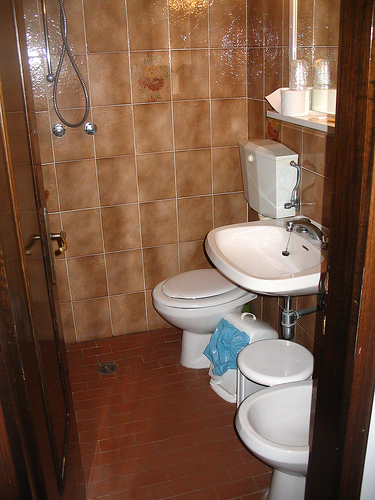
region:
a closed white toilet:
[152, 267, 255, 370]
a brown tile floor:
[75, 402, 216, 494]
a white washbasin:
[203, 217, 335, 294]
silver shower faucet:
[37, 0, 106, 136]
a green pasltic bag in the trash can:
[203, 318, 253, 376]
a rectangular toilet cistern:
[230, 135, 301, 218]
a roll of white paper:
[264, 87, 309, 115]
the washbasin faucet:
[285, 218, 321, 245]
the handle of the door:
[46, 231, 66, 251]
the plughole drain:
[101, 362, 114, 374]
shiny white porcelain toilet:
[146, 259, 259, 373]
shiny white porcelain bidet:
[234, 374, 331, 498]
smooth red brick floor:
[47, 326, 275, 499]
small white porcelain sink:
[189, 205, 328, 297]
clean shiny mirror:
[292, 0, 346, 123]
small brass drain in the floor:
[94, 354, 118, 375]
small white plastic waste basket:
[203, 311, 280, 407]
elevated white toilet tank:
[234, 135, 302, 223]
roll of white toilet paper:
[263, 80, 312, 119]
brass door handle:
[47, 226, 69, 261]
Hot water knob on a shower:
[52, 124, 65, 135]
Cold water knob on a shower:
[83, 121, 96, 135]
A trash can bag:
[205, 319, 248, 375]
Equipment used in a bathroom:
[234, 337, 313, 405]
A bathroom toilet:
[233, 379, 320, 499]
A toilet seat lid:
[153, 267, 247, 306]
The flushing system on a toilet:
[237, 139, 299, 217]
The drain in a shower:
[98, 361, 118, 374]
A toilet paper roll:
[264, 87, 310, 115]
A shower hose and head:
[40, 0, 89, 126]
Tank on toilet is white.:
[237, 140, 297, 207]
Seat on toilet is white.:
[164, 263, 233, 316]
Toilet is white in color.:
[153, 260, 199, 370]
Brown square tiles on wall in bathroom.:
[79, 198, 169, 259]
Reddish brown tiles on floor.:
[102, 396, 182, 463]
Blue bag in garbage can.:
[212, 320, 246, 367]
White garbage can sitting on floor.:
[210, 315, 253, 418]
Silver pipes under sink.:
[279, 296, 307, 339]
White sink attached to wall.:
[238, 229, 316, 285]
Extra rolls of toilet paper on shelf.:
[274, 81, 328, 111]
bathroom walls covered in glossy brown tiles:
[8, 3, 335, 344]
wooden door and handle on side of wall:
[0, 1, 71, 492]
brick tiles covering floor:
[66, 327, 267, 494]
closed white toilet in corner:
[150, 261, 265, 368]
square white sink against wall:
[207, 198, 321, 292]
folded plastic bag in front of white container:
[206, 306, 272, 405]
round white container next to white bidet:
[233, 335, 308, 494]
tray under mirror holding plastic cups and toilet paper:
[265, 0, 335, 132]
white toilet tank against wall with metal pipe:
[232, 131, 297, 211]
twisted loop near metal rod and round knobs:
[37, 0, 99, 137]